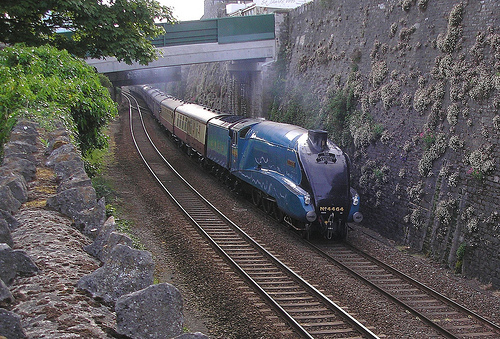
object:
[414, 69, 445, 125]
moss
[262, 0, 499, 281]
rocks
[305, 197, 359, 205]
lights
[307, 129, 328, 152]
shaft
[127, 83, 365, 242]
cars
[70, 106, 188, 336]
side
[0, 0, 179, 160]
bushes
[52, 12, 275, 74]
bridge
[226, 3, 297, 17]
roof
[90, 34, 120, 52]
windows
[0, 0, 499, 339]
canyon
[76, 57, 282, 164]
tunnel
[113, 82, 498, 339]
rails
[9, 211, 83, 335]
path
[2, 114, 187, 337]
ledge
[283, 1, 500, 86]
plants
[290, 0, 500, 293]
cliff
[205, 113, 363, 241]
engine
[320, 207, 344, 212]
number